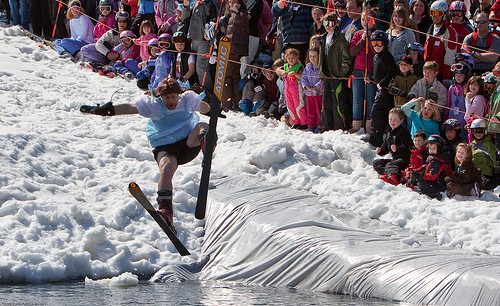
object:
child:
[372, 107, 411, 185]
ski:
[128, 182, 189, 256]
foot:
[157, 210, 173, 226]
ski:
[195, 36, 232, 220]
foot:
[202, 128, 218, 154]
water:
[0, 282, 427, 306]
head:
[159, 79, 178, 109]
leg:
[158, 156, 178, 190]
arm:
[115, 103, 150, 114]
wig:
[159, 79, 181, 95]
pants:
[306, 94, 321, 126]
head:
[388, 108, 404, 128]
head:
[309, 49, 319, 62]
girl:
[301, 47, 323, 130]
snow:
[268, 210, 364, 268]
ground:
[0, 129, 499, 273]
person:
[352, 8, 377, 133]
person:
[172, 36, 196, 78]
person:
[55, 0, 94, 55]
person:
[408, 62, 448, 109]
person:
[451, 143, 483, 196]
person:
[132, 20, 157, 61]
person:
[401, 131, 428, 188]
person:
[470, 120, 500, 191]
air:
[0, 202, 119, 278]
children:
[285, 49, 305, 129]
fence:
[56, 1, 500, 123]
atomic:
[216, 46, 228, 94]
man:
[79, 79, 217, 226]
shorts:
[153, 138, 202, 165]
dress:
[135, 91, 203, 147]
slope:
[0, 31, 366, 281]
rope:
[208, 55, 365, 79]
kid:
[368, 30, 396, 145]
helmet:
[371, 30, 388, 39]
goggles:
[371, 40, 381, 46]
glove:
[79, 101, 115, 116]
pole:
[362, 6, 368, 127]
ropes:
[290, 0, 368, 15]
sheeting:
[198, 181, 500, 305]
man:
[463, 13, 499, 69]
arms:
[478, 34, 500, 62]